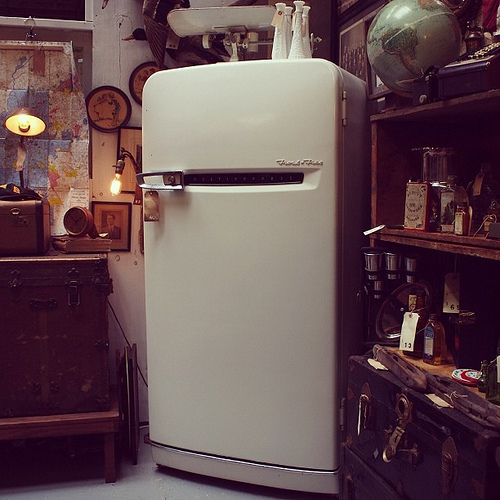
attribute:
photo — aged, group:
[334, 31, 377, 96]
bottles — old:
[404, 173, 472, 234]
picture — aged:
[92, 96, 124, 121]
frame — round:
[85, 86, 130, 132]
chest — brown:
[5, 193, 55, 254]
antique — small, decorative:
[406, 310, 494, 400]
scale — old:
[170, 2, 290, 64]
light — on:
[2, 107, 50, 197]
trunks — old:
[4, 201, 129, 421]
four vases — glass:
[261, 0, 319, 61]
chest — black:
[334, 347, 499, 497]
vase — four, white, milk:
[269, 1, 288, 58]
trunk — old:
[301, 319, 482, 498]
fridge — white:
[108, 26, 408, 496]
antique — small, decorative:
[370, 345, 430, 392]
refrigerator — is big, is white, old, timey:
[120, 56, 378, 494]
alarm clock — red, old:
[60, 206, 92, 236]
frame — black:
[82, 189, 189, 263]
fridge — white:
[84, 52, 400, 492]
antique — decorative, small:
[400, 177, 431, 227]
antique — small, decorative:
[400, 177, 435, 231]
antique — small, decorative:
[399, 175, 431, 230]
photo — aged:
[97, 207, 125, 237]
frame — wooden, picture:
[90, 200, 131, 254]